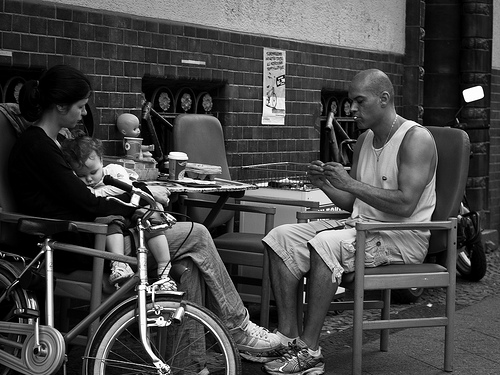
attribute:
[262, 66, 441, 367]
man — sitting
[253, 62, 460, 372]
man — cigarette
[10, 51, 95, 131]
woman — head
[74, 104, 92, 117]
woman — nose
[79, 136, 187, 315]
child — head, dark hair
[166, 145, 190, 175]
cup — disposable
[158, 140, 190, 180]
cup — disposable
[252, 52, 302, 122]
picture — black,  white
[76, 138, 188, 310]
baby — sleeping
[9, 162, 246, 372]
bike — silver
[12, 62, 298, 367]
woman —  dark hair, dark hair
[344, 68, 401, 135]
head — man`s,  bald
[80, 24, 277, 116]
wall — bricks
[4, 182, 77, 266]
seat — black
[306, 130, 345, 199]
man —  rolling something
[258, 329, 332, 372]
man —  sneakers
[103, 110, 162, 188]
babydoll — bald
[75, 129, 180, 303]
child — sleeping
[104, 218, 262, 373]
woman —  jeans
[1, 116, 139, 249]
woman —  dark shirt